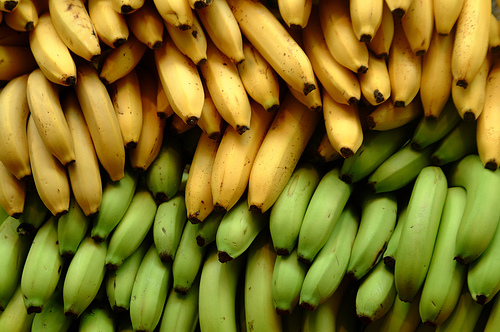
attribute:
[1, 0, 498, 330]
bananas — green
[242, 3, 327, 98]
banana — ripe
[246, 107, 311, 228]
banana — ripe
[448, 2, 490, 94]
banana — ripe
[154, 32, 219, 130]
banana — ripe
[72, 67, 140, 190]
banana — ripe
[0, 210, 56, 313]
banana — green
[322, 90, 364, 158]
banana — ripe , hanging 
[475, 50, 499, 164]
banana — ripe , hanging 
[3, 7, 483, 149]
bananas — yellow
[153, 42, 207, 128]
banana — ripe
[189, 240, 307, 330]
bananas — green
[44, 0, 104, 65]
banana — yellow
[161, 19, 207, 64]
banana — yellow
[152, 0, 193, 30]
banana — yellow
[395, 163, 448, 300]
banana — green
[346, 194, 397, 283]
banana — green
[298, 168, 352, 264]
banana — green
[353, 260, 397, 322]
banana — green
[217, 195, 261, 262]
banana — green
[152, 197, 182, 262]
banana — green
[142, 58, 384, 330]
fruit — yellow, green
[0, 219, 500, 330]
green bananas — light green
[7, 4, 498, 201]
yellow bananas — yellow 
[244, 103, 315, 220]
banana — ripe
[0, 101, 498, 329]
green bananas — bunched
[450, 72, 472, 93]
brown end — brown 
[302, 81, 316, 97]
brown end — brown 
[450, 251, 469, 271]
brown end — brown 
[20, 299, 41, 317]
brown end — brown 